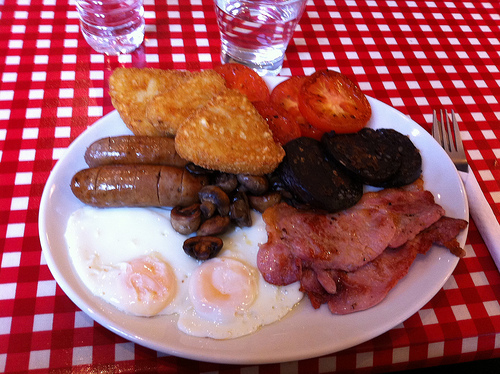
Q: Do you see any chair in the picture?
A: No, there are no chairs.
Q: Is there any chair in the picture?
A: No, there are no chairs.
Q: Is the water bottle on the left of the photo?
A: Yes, the water bottle is on the left of the image.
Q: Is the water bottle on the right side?
A: No, the water bottle is on the left of the image.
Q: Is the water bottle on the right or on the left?
A: The water bottle is on the left of the image.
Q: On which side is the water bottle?
A: The water bottle is on the left of the image.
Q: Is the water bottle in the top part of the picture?
A: Yes, the water bottle is in the top of the image.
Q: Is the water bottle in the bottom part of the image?
A: No, the water bottle is in the top of the image.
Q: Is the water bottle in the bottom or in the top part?
A: The water bottle is in the top of the image.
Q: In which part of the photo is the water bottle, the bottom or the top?
A: The water bottle is in the top of the image.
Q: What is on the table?
A: The water bottle is on the table.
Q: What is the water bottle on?
A: The water bottle is on the table.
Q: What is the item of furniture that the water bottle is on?
A: The piece of furniture is a table.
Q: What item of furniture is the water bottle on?
A: The water bottle is on the table.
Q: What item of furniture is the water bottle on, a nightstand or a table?
A: The water bottle is on a table.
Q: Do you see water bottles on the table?
A: Yes, there is a water bottle on the table.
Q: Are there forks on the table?
A: No, there is a water bottle on the table.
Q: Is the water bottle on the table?
A: Yes, the water bottle is on the table.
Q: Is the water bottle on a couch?
A: No, the water bottle is on the table.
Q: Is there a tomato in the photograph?
A: Yes, there is a tomato.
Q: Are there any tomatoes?
A: Yes, there is a tomato.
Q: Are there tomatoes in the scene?
A: Yes, there is a tomato.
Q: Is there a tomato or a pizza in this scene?
A: Yes, there is a tomato.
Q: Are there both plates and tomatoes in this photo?
A: Yes, there are both a tomato and a plate.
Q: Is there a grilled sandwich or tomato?
A: Yes, there is a grilled tomato.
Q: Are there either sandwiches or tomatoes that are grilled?
A: Yes, the tomato is grilled.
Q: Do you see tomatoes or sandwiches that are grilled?
A: Yes, the tomato is grilled.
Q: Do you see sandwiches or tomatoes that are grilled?
A: Yes, the tomato is grilled.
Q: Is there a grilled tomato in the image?
A: Yes, there is a grilled tomato.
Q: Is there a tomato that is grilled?
A: Yes, there is a tomato that is grilled.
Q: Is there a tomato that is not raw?
A: Yes, there is a grilled tomato.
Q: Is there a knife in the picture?
A: No, there are no knives.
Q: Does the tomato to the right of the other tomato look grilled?
A: Yes, the tomato is grilled.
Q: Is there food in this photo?
A: Yes, there is food.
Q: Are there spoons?
A: No, there are no spoons.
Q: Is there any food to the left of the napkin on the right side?
A: Yes, there is food to the left of the napkin.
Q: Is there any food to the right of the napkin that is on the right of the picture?
A: No, the food is to the left of the napkin.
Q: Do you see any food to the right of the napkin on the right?
A: No, the food is to the left of the napkin.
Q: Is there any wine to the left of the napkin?
A: No, there is food to the left of the napkin.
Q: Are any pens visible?
A: No, there are no pens.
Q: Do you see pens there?
A: No, there are no pens.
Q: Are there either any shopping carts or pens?
A: No, there are no pens or shopping carts.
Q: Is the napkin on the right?
A: Yes, the napkin is on the right of the image.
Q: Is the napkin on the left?
A: No, the napkin is on the right of the image.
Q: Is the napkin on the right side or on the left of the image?
A: The napkin is on the right of the image.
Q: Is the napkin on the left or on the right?
A: The napkin is on the right of the image.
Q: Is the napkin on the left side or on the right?
A: The napkin is on the right of the image.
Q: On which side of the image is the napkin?
A: The napkin is on the right of the image.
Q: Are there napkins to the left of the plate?
A: No, the napkin is to the right of the plate.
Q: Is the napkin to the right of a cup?
A: No, the napkin is to the right of the plate.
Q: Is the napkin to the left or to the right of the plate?
A: The napkin is to the right of the plate.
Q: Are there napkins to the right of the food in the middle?
A: Yes, there is a napkin to the right of the food.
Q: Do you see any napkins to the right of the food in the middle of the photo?
A: Yes, there is a napkin to the right of the food.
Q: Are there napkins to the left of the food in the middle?
A: No, the napkin is to the right of the food.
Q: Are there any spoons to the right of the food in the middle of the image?
A: No, there is a napkin to the right of the food.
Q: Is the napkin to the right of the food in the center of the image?
A: Yes, the napkin is to the right of the food.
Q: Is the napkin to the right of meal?
A: No, the napkin is to the right of the food.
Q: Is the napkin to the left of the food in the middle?
A: No, the napkin is to the right of the food.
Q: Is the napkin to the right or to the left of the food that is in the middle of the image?
A: The napkin is to the right of the food.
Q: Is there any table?
A: Yes, there is a table.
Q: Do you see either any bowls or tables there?
A: Yes, there is a table.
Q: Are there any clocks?
A: No, there are no clocks.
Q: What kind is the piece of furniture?
A: The piece of furniture is a table.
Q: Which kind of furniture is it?
A: The piece of furniture is a table.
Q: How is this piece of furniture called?
A: This is a table.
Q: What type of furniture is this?
A: This is a table.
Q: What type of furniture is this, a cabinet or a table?
A: This is a table.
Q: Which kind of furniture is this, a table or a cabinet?
A: This is a table.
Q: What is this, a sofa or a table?
A: This is a table.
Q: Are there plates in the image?
A: Yes, there is a plate.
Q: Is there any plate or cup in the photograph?
A: Yes, there is a plate.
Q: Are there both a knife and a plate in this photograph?
A: No, there is a plate but no knives.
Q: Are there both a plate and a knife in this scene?
A: No, there is a plate but no knives.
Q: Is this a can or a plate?
A: This is a plate.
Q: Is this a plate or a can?
A: This is a plate.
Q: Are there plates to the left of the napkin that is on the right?
A: Yes, there is a plate to the left of the napkin.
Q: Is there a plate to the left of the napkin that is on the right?
A: Yes, there is a plate to the left of the napkin.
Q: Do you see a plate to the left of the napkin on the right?
A: Yes, there is a plate to the left of the napkin.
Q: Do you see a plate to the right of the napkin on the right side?
A: No, the plate is to the left of the napkin.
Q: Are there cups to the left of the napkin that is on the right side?
A: No, there is a plate to the left of the napkin.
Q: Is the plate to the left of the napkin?
A: Yes, the plate is to the left of the napkin.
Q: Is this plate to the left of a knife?
A: No, the plate is to the left of the napkin.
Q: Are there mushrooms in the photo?
A: Yes, there are mushrooms.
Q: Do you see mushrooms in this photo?
A: Yes, there are mushrooms.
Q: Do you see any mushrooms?
A: Yes, there are mushrooms.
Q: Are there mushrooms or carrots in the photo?
A: Yes, there are mushrooms.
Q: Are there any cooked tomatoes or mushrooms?
A: Yes, there are cooked mushrooms.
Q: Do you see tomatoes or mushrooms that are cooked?
A: Yes, the mushrooms are cooked.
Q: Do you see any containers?
A: No, there are no containers.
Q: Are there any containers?
A: No, there are no containers.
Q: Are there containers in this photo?
A: No, there are no containers.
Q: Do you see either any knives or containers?
A: No, there are no containers or knives.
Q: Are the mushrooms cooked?
A: Yes, the mushrooms are cooked.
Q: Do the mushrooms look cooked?
A: Yes, the mushrooms are cooked.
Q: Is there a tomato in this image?
A: Yes, there is a tomato.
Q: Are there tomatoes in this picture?
A: Yes, there is a tomato.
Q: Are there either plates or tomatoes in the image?
A: Yes, there is a tomato.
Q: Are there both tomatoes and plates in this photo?
A: Yes, there are both a tomato and a plate.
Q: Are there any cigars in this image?
A: No, there are no cigars.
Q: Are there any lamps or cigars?
A: No, there are no cigars or lamps.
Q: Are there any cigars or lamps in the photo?
A: No, there are no cigars or lamps.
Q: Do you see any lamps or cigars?
A: No, there are no cigars or lamps.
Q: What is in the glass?
A: The water is in the glass.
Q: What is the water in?
A: The water is in the glass.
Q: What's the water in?
A: The water is in the glass.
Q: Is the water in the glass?
A: Yes, the water is in the glass.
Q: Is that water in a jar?
A: No, the water is in the glass.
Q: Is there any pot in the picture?
A: No, there are no pots.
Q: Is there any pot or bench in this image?
A: No, there are no pots or benches.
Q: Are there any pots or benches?
A: No, there are no pots or benches.